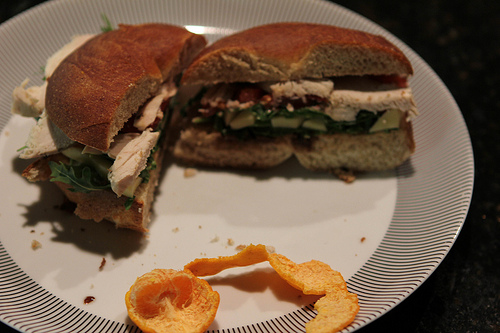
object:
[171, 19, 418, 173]
burger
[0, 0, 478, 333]
plate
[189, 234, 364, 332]
peel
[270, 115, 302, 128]
veggies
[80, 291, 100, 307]
sauce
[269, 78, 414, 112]
chicken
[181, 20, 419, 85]
bread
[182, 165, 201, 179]
crumb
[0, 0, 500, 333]
counter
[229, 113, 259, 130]
cucumber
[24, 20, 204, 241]
burger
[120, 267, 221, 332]
clementine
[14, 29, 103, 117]
chicken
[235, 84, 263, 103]
tomato